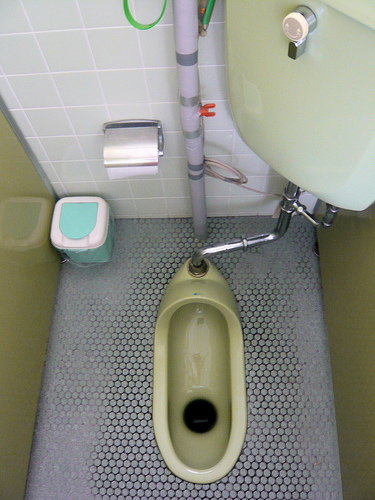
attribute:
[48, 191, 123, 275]
trashcan — teal, white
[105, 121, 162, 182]
paper holder — stainless steel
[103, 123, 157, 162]
paper protector — stainless steel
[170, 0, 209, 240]
pipe — long, gray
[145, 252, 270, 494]
toilet — vanilla-colored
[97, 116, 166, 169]
holder — metal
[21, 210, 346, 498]
floor — octagonal, dirty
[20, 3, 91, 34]
tile — white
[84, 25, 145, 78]
tile — white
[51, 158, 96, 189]
tile — white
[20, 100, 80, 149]
tile — white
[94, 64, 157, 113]
tile — white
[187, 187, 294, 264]
pipe — bright, silver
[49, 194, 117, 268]
receptacle — white, aqua, plastic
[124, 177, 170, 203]
tile — white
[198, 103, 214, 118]
knob — red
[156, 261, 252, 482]
toilet — squat style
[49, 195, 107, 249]
lid — flip style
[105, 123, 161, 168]
holder — metal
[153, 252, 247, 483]
toilet — Eastern style, squat toilet